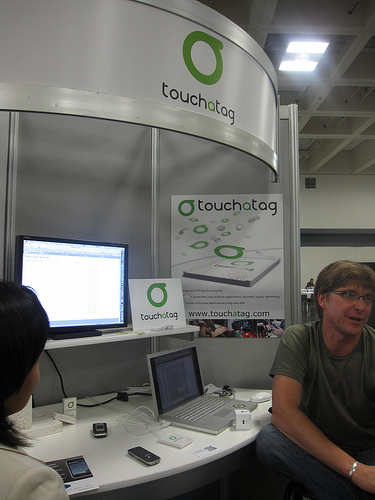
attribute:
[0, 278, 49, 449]
hair — black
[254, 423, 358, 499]
jeans — blue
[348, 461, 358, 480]
bracelet — silver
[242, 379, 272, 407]
mouse — white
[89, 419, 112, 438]
cellphone — flip top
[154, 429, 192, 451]
touch pad — white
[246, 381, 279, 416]
mouse — white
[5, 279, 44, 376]
hair — dark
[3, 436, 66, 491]
jacket — white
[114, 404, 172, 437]
cable — white, tangled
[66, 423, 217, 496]
desk — white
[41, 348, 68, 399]
long cord — black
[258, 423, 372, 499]
leg — crossed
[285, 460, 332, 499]
leg — crossed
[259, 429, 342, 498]
jeans — blue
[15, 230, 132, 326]
screen — lit up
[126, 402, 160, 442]
cords — tangled, electrical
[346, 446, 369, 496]
bracelet — silver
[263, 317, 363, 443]
shirt — green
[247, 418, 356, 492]
jeans — blue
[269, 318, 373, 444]
shirt — green